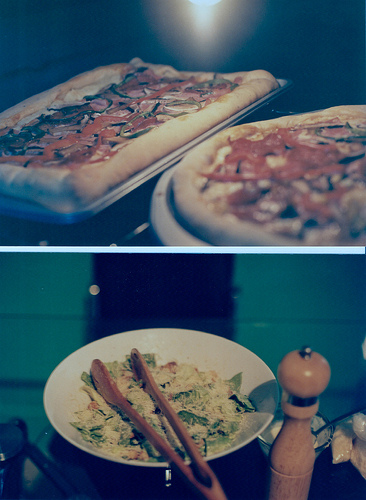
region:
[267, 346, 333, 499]
a an pepper grinder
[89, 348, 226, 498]
tan salad tongs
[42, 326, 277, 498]
salad tongs on a white plate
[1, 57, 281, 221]
rectangular pizza on a metal tray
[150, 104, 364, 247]
round pizza on a metal tray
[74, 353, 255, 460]
lots of cheese on a sald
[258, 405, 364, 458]
a spoon in a bowl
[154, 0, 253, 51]
a very bright light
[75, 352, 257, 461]
green salad leaves on a plate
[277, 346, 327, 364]
a silver top on the pepper grinder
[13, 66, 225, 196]
Pizza on a pan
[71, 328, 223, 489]
Tongs in a salad bowl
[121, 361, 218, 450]
salad in a white bowl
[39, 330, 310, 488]
white bowl on the table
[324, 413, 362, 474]
plastic bag on the table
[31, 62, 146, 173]
vegetable on a pizza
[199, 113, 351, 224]
Pizza on a pan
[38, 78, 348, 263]
Pizza on a pan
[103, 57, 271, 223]
Pizza on a pan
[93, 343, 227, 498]
The wooden tongs on the plate.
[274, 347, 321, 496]
The wooden pepper dispenser.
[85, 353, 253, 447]
The green leaves in the bowl.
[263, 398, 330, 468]
The small glass bowl on the right.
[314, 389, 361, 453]
The spoon in the small glass bowl.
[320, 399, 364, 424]
The handle of the spoon in the small glass bowl.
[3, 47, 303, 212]
The pizza on the left.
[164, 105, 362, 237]
The pizza on the right.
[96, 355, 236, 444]
The salad in the bowl.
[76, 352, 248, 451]
The shredded cheese on the salad.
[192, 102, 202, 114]
edge of a pizza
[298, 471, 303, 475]
aprt of a line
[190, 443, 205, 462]
part of a handkle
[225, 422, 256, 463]
dge iof a plate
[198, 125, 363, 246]
round pizza on plate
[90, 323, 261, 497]
wooden tongs on plate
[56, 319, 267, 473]
salad in white bowl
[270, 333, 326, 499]
salt and pepper shaker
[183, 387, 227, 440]
lettuce in the salad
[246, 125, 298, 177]
pepperoni on the pizza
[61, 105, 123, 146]
chopped tomato on pizza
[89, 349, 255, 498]
Tongs and food on a plate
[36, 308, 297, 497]
Tongs and food on a plate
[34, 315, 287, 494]
Tongs and food on a plate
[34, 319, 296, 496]
Tongs and food on a plate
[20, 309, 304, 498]
Tongs and food on a plate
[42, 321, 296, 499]
Tongs and food on a plate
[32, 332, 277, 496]
Tongs and food on a plate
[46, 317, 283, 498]
Tongs and food on a plate